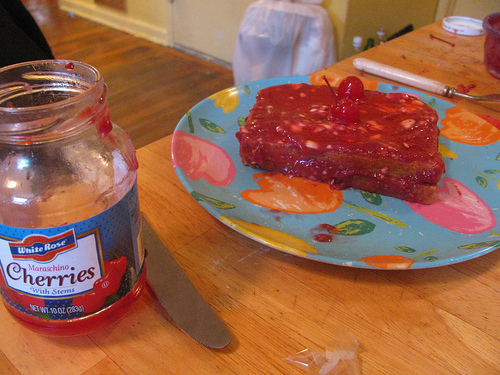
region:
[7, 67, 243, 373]
a jar of cherry jam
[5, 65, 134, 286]
a jar of cherry jam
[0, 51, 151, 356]
glass jar that is empty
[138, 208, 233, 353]
blade of a butter knife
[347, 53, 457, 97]
handle of a fork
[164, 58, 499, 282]
plate with food on it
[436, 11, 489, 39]
white metal jar lid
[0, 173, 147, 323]
label on a jar of food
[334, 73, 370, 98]
a small red cherry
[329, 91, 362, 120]
a small red cherry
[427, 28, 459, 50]
stem of a cherry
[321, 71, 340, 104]
stem of a cherry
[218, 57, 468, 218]
A piece of bread with jam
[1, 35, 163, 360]
A jar of maraschino cherries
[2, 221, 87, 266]
A White Rose logo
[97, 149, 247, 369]
A knife on a table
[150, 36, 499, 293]
A floral plate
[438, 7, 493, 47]
The lid of a jar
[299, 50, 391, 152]
Cherries on a piece of bread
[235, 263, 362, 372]
a wooden tabletop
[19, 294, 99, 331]
The weight label on a jar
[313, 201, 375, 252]
a leaf on a plate with a jam stain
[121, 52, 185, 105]
the wooden floor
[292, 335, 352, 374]
a piece of clear plastic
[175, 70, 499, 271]
a round blue plate with designs on it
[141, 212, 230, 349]
the top of the butter knife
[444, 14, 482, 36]
the white cover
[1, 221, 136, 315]
the cherry jar label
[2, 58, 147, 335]
the clear glass bottle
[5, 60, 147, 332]
the clear empty glass bottle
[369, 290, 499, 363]
the top of the wooden table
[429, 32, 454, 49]
the cherry stem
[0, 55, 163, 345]
empty jar of cherries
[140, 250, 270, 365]
knife on table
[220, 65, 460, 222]
Cherry dessert with white flecks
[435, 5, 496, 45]
lid to cherry jar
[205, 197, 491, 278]
floral patterned plate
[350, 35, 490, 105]
fork on table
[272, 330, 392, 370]
cellophane on the table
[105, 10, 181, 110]
wood floor and base board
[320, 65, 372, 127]
Two cherries on top of desert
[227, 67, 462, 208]
Cherries and bread dessert